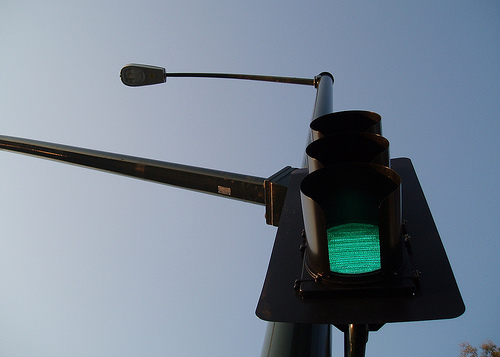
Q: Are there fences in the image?
A: No, there are no fences.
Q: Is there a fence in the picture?
A: No, there are no fences.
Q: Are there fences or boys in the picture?
A: No, there are no fences or boys.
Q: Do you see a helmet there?
A: No, there are no helmets.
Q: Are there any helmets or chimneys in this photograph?
A: No, there are no helmets or chimneys.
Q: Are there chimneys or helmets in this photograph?
A: No, there are no helmets or chimneys.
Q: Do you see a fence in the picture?
A: No, there are no fences.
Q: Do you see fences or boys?
A: No, there are no fences or boys.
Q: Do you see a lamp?
A: Yes, there is a lamp.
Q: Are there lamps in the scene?
A: Yes, there is a lamp.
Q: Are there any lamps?
A: Yes, there is a lamp.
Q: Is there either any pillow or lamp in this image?
A: Yes, there is a lamp.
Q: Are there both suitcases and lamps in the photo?
A: No, there is a lamp but no suitcases.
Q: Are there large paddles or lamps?
A: Yes, there is a large lamp.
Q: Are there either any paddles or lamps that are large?
A: Yes, the lamp is large.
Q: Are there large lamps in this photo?
A: Yes, there is a large lamp.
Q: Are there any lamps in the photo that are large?
A: Yes, there is a lamp that is large.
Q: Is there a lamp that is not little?
A: Yes, there is a large lamp.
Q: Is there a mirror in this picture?
A: No, there are no mirrors.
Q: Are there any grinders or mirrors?
A: No, there are no mirrors or grinders.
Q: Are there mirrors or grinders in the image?
A: No, there are no mirrors or grinders.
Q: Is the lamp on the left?
A: Yes, the lamp is on the left of the image.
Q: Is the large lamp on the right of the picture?
A: No, the lamp is on the left of the image.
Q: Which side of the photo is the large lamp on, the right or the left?
A: The lamp is on the left of the image.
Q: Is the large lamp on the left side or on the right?
A: The lamp is on the left of the image.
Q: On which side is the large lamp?
A: The lamp is on the left of the image.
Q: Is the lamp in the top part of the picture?
A: Yes, the lamp is in the top of the image.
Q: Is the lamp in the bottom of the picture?
A: No, the lamp is in the top of the image.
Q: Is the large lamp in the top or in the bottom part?
A: The lamp is in the top of the image.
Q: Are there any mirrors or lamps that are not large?
A: No, there is a lamp but it is large.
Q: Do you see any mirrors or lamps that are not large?
A: No, there is a lamp but it is large.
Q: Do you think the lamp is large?
A: Yes, the lamp is large.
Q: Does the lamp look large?
A: Yes, the lamp is large.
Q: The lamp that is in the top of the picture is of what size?
A: The lamp is large.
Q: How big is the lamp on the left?
A: The lamp is large.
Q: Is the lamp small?
A: No, the lamp is large.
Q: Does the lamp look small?
A: No, the lamp is large.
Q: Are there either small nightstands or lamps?
A: No, there is a lamp but it is large.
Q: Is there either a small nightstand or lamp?
A: No, there is a lamp but it is large.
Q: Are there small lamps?
A: No, there is a lamp but it is large.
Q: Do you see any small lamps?
A: No, there is a lamp but it is large.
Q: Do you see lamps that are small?
A: No, there is a lamp but it is large.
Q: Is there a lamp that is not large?
A: No, there is a lamp but it is large.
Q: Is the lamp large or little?
A: The lamp is large.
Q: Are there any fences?
A: No, there are no fences.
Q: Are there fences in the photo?
A: No, there are no fences.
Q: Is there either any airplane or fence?
A: No, there are no fences or airplanes.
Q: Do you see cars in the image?
A: No, there are no cars.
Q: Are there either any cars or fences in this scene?
A: No, there are no cars or fences.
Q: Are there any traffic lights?
A: Yes, there is a traffic light.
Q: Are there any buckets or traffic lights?
A: Yes, there is a traffic light.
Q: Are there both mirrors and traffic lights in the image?
A: No, there is a traffic light but no mirrors.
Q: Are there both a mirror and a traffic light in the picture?
A: No, there is a traffic light but no mirrors.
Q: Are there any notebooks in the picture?
A: No, there are no notebooks.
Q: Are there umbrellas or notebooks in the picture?
A: No, there are no notebooks or umbrellas.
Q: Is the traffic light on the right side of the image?
A: Yes, the traffic light is on the right of the image.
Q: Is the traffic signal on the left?
A: No, the traffic signal is on the right of the image.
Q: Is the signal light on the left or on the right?
A: The signal light is on the right of the image.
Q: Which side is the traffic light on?
A: The traffic light is on the right of the image.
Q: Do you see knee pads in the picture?
A: No, there are no knee pads.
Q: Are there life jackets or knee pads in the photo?
A: No, there are no knee pads or life jackets.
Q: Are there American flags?
A: No, there are no American flags.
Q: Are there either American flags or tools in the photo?
A: No, there are no American flags or tools.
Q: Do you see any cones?
A: No, there are no cones.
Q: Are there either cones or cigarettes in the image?
A: No, there are no cones or cigarettes.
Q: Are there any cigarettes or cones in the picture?
A: No, there are no cones or cigarettes.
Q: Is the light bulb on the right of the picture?
A: Yes, the light bulb is on the right of the image.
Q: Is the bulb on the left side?
A: No, the bulb is on the right of the image.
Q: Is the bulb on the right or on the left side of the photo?
A: The bulb is on the right of the image.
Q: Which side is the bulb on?
A: The bulb is on the right of the image.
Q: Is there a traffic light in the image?
A: Yes, there is a traffic light.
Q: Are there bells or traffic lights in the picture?
A: Yes, there is a traffic light.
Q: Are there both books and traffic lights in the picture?
A: No, there is a traffic light but no books.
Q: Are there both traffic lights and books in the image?
A: No, there is a traffic light but no books.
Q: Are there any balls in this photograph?
A: No, there are no balls.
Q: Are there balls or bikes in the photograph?
A: No, there are no balls or bikes.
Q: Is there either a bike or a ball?
A: No, there are no balls or bikes.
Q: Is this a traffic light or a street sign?
A: This is a traffic light.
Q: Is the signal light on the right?
A: Yes, the signal light is on the right of the image.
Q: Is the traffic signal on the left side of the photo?
A: No, the traffic signal is on the right of the image.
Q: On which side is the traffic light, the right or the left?
A: The traffic light is on the right of the image.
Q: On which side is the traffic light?
A: The traffic light is on the right of the image.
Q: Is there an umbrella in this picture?
A: No, there are no umbrellas.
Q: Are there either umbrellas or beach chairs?
A: No, there are no umbrellas or beach chairs.